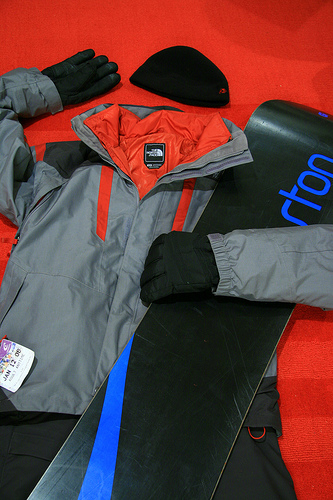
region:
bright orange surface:
[179, 10, 295, 39]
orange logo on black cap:
[212, 84, 229, 96]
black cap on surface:
[122, 45, 239, 100]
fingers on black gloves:
[60, 44, 125, 96]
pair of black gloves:
[28, 42, 130, 102]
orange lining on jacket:
[83, 170, 120, 240]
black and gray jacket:
[33, 133, 119, 237]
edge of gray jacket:
[207, 228, 235, 304]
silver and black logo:
[133, 131, 172, 160]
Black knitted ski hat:
[124, 42, 237, 110]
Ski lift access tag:
[0, 335, 38, 396]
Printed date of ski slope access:
[1, 346, 22, 381]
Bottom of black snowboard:
[19, 100, 331, 495]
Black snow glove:
[134, 231, 220, 308]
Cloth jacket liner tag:
[142, 141, 168, 170]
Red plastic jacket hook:
[245, 424, 267, 440]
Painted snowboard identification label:
[277, 152, 331, 229]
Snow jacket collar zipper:
[87, 145, 248, 181]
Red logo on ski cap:
[215, 85, 229, 97]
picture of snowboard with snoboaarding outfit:
[4, 17, 324, 498]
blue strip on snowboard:
[74, 316, 150, 497]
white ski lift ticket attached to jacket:
[0, 334, 36, 394]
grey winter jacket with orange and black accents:
[8, 42, 322, 416]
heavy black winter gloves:
[133, 219, 220, 305]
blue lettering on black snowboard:
[275, 142, 332, 239]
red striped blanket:
[282, 339, 331, 485]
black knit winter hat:
[127, 42, 234, 112]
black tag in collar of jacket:
[138, 135, 170, 175]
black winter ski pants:
[1, 413, 288, 497]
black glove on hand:
[127, 243, 220, 289]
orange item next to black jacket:
[289, 348, 330, 498]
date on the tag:
[0, 351, 35, 390]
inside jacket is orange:
[81, 117, 201, 154]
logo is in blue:
[279, 162, 332, 234]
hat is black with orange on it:
[143, 47, 225, 106]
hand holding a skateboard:
[130, 203, 285, 499]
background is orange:
[5, 0, 330, 54]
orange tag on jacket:
[249, 428, 276, 448]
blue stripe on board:
[87, 344, 128, 499]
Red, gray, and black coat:
[20, 109, 146, 349]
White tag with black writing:
[1, 344, 25, 384]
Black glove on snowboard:
[138, 228, 213, 301]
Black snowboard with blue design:
[81, 350, 217, 484]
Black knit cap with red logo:
[146, 49, 230, 102]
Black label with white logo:
[143, 140, 164, 169]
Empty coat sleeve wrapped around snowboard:
[160, 215, 309, 305]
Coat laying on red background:
[76, 104, 232, 196]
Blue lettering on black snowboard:
[279, 156, 328, 224]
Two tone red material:
[281, 342, 324, 464]